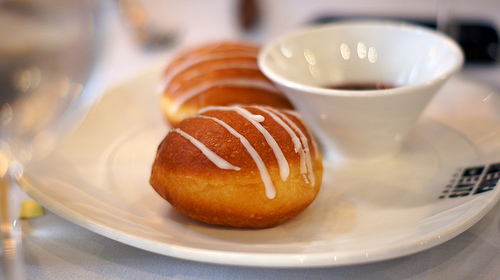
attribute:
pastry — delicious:
[157, 38, 292, 125]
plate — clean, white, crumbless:
[21, 54, 497, 264]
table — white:
[4, 2, 497, 274]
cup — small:
[260, 17, 479, 149]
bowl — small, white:
[249, 23, 488, 169]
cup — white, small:
[260, 22, 488, 162]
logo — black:
[441, 159, 499, 199]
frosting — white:
[181, 107, 306, 189]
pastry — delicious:
[143, 101, 328, 231]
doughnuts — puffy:
[140, 95, 331, 235]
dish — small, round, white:
[374, 163, 410, 220]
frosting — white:
[157, 49, 321, 201]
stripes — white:
[164, 103, 319, 202]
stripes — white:
[153, 45, 281, 120]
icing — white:
[173, 127, 240, 170]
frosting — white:
[197, 106, 312, 169]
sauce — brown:
[315, 79, 409, 93]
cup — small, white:
[255, 18, 467, 163]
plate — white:
[2, 62, 498, 270]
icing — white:
[157, 81, 289, 123]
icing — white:
[221, 121, 291, 208]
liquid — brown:
[321, 77, 398, 90]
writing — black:
[437, 158, 498, 198]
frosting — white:
[170, 102, 314, 201]